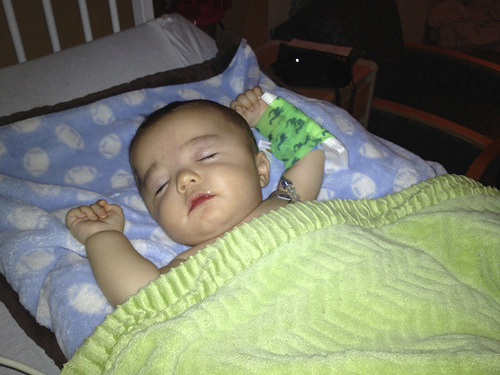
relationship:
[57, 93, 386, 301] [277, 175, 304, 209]
baby has iv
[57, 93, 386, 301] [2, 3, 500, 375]
baby sleeping in bed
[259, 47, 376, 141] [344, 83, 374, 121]
table with drawer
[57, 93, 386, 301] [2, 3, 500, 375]
baby laying in a bed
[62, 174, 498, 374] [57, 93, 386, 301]
blanket on top of baby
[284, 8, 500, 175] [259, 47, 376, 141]
armchair next to table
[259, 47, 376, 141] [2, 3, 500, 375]
table next to bed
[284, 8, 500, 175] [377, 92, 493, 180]
armchair has arm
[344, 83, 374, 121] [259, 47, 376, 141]
drawer inside table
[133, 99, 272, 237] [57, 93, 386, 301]
head of baby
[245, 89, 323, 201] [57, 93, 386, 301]
arm of baby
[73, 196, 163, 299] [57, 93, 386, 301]
arm of baby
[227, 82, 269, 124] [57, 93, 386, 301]
hand of baby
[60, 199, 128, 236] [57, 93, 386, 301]
hand of baby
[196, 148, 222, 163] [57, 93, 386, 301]
eye of baby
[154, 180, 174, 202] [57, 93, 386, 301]
eye of baby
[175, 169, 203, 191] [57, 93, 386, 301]
nose of baby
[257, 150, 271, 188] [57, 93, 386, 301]
ear of baby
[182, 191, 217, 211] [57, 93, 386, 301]
mouth of baby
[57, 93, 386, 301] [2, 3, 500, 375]
baby laying on bed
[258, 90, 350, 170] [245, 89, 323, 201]
cast on arm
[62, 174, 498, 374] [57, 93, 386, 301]
blanket covering baby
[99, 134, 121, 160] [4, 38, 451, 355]
football on blanket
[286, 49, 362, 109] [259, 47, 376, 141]
telephone on table